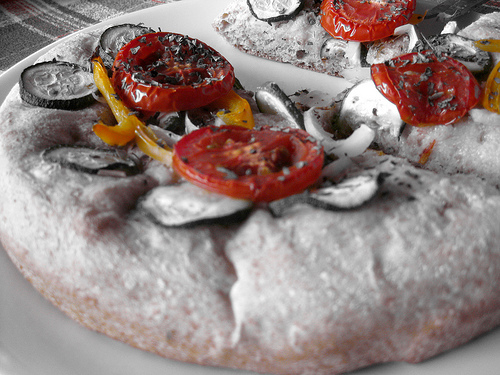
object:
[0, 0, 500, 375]
bread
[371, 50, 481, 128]
tomato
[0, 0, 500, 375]
plate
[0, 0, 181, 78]
cloth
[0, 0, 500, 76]
table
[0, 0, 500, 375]
pizza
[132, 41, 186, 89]
basil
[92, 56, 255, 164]
peppers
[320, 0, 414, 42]
tomato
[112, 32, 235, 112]
cut tomato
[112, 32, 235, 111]
tomato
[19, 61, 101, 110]
veggies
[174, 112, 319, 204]
tomato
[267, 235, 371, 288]
white